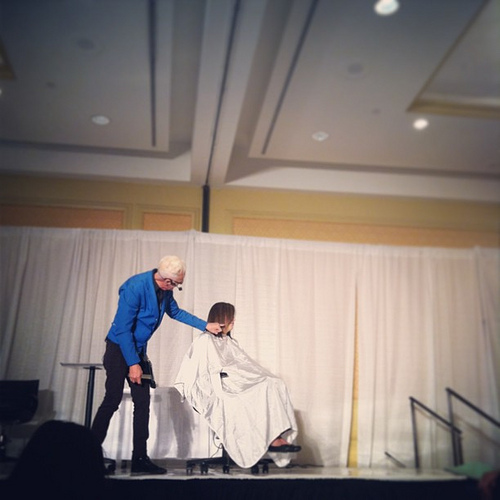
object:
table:
[61, 362, 104, 427]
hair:
[166, 258, 177, 274]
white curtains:
[9, 238, 73, 334]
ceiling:
[428, 14, 495, 181]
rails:
[402, 387, 429, 467]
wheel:
[261, 463, 271, 473]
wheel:
[251, 465, 260, 475]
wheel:
[219, 464, 232, 472]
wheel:
[201, 465, 210, 475]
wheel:
[186, 464, 196, 473]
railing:
[441, 386, 499, 467]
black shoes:
[270, 445, 302, 452]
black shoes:
[129, 452, 169, 474]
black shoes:
[99, 457, 117, 474]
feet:
[269, 433, 299, 450]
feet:
[130, 450, 167, 472]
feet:
[99, 453, 116, 471]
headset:
[162, 274, 181, 295]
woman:
[183, 300, 300, 452]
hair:
[204, 295, 233, 335]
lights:
[410, 112, 439, 134]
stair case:
[438, 380, 498, 493]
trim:
[0, 169, 90, 252]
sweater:
[100, 267, 214, 372]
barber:
[79, 255, 224, 478]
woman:
[173, 299, 301, 474]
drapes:
[446, 246, 497, 401]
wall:
[186, 174, 282, 226]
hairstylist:
[91, 255, 224, 475]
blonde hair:
[158, 254, 185, 274]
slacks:
[91, 338, 151, 455]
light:
[408, 115, 433, 142]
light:
[310, 123, 330, 145]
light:
[370, 0, 405, 21]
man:
[87, 252, 225, 476]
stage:
[386, 454, 447, 498]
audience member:
[5, 413, 118, 497]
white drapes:
[312, 271, 364, 332]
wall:
[270, 173, 327, 238]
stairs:
[406, 395, 433, 493]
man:
[79, 246, 226, 475]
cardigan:
[104, 268, 206, 368]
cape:
[174, 324, 300, 471]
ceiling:
[14, 6, 62, 181]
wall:
[451, 201, 498, 249]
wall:
[1, 164, 41, 250]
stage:
[175, 462, 248, 498]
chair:
[179, 369, 303, 482]